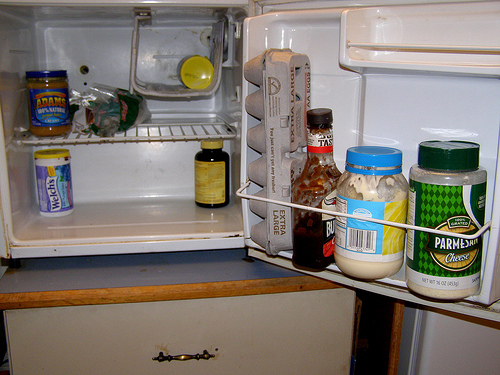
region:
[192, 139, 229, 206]
A bottle of vitamins in fridge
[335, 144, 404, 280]
A jar of mayonase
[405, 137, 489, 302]
A jar of parmesan cheese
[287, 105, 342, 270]
A bottle of barbecue sauce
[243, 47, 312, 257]
A carton of eggs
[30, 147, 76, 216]
A container of welch's drink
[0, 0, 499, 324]
A small sized refrigerator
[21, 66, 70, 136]
A jar of yellow sauce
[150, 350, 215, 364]
A metal drawer handle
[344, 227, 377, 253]
A barcode on jar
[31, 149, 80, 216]
can of juice on bottom shelf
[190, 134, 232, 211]
vitamins on the shelf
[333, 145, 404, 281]
mayonaise on the door shelf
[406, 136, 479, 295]
bottle of cheese on door shelf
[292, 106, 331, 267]
barbecue bottle on the door shelf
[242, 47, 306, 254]
carton of eggs on the door shelf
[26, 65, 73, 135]
jar of sauce on top shelf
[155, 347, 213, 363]
handle attached to drawer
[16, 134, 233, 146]
top refrigerator shelf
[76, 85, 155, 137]
bag of food on top shelf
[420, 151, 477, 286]
cheese bottle in fridge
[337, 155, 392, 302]
mayo bottle in fridge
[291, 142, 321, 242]
bbq bottle in fridge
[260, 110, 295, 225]
egg carton in fridge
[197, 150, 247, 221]
pill bottle in fridge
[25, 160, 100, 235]
juice can in fridge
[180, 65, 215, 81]
yellow lid on bottle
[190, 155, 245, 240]
yellow label on bottle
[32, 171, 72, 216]
purple letters on can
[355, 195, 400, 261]
blue label on jar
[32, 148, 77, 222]
Welchs grape juice in the fridge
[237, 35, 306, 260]
an egg carton standing up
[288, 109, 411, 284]
condiments in the fridge door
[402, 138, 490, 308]
grated parmasean cheese in the fridge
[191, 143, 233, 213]
a pill bottle in the fridge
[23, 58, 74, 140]
a jar of salsa with a blue lable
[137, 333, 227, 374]
the handle of the drawer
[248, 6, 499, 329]
the open door of the fridge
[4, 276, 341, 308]
the wooden seal on the counter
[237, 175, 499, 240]
the bar on the fridge door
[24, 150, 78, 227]
Can juice in fridge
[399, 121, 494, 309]
Jar of cheese on fridge door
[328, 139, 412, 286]
Jar of mayonaise on door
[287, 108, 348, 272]
Bottle of sauce on door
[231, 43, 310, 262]
Carton of eggs on door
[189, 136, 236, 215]
Black jar in the fridge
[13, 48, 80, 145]
Jar of salsa in the fridge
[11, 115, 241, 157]
Rack in the fridge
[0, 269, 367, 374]
Counter under the fridge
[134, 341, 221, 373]
Handle on the counter